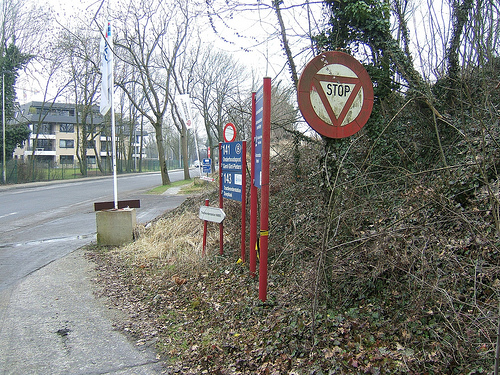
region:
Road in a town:
[0, 164, 217, 293]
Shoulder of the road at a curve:
[0, 251, 164, 373]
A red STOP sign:
[297, 51, 374, 138]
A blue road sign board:
[255, 83, 260, 184]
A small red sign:
[222, 125, 232, 140]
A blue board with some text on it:
[220, 142, 240, 197]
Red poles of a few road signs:
[200, 75, 270, 297]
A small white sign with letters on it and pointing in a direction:
[199, 203, 224, 222]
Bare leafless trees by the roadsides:
[2, 0, 295, 186]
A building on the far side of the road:
[14, 102, 147, 164]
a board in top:
[277, 45, 402, 166]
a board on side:
[230, 112, 308, 325]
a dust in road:
[46, 311, 103, 366]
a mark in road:
[25, 305, 90, 366]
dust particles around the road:
[173, 273, 290, 363]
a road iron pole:
[253, 96, 295, 316]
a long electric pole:
[70, 25, 169, 272]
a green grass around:
[338, 105, 495, 335]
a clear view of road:
[17, 173, 104, 271]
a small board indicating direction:
[179, 183, 231, 240]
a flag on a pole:
[85, 15, 153, 132]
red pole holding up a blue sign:
[250, 77, 275, 307]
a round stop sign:
[288, 26, 392, 158]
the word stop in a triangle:
[305, 72, 370, 130]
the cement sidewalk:
[31, 243, 145, 370]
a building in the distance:
[9, 71, 154, 187]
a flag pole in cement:
[85, 190, 157, 274]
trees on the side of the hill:
[342, 16, 479, 157]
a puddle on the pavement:
[23, 232, 93, 251]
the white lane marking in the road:
[1, 200, 61, 220]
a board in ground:
[292, 37, 434, 182]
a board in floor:
[302, 50, 404, 262]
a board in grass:
[278, 63, 430, 363]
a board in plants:
[267, 52, 397, 354]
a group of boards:
[177, 73, 473, 310]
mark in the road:
[41, 315, 83, 360]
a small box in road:
[74, 198, 152, 260]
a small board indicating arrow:
[190, 186, 255, 251]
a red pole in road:
[247, 90, 309, 306]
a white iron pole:
[93, 40, 152, 188]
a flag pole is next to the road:
[93, 5, 137, 214]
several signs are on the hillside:
[189, 40, 364, 277]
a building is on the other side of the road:
[17, 98, 144, 172]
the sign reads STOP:
[293, 41, 378, 144]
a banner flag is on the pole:
[171, 91, 197, 141]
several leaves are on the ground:
[151, 281, 392, 372]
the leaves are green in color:
[336, 0, 414, 58]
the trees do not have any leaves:
[9, 5, 225, 94]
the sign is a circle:
[295, 39, 377, 149]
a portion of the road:
[1, 164, 203, 282]